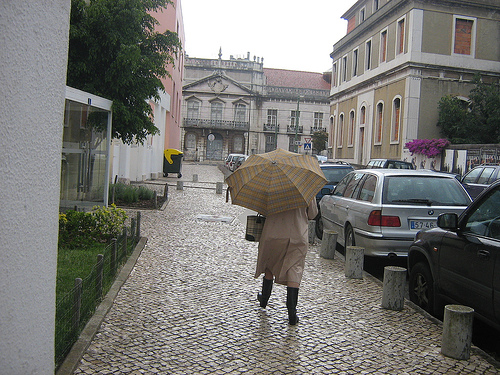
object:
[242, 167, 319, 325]
person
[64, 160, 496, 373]
sidewalk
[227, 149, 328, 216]
umbrella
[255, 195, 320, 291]
coat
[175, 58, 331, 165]
building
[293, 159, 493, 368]
street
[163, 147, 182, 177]
bin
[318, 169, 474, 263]
car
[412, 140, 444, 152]
flowers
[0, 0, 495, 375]
wall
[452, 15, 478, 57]
window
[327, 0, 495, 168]
building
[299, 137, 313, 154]
street sign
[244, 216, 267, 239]
bag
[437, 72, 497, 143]
tree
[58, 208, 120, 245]
bush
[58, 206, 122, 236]
flowers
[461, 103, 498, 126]
leaves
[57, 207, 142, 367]
fence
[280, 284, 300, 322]
boots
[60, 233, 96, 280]
grass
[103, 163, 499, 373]
cobblestones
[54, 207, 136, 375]
garden